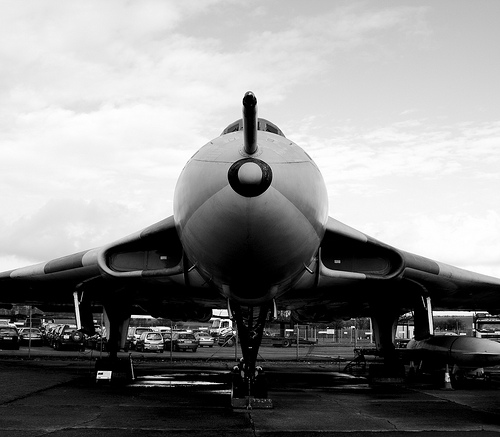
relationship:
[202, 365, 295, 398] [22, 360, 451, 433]
wheels on ground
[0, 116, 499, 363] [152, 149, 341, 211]
plane in white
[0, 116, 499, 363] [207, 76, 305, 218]
plane has sharphead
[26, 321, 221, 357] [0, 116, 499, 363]
cars parked behind plane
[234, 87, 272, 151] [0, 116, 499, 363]
nose of airplane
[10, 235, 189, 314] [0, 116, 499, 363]
leftarm of airplane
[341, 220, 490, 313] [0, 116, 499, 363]
rightarm of airplane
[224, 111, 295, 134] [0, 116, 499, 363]
windows on airplane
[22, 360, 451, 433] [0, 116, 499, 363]
landingpoint for airplane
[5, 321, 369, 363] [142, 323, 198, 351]
parkinglot for vehicles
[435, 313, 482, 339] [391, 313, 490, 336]
frontview of schoolbus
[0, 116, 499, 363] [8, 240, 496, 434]
airplane at airport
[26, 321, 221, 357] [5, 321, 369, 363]
cars parked in parkinglot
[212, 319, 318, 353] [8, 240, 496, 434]
largetruck at airport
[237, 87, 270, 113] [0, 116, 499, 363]
fronttip of airplane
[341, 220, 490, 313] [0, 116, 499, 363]
wing of airplane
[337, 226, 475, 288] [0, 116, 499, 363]
wing on airplane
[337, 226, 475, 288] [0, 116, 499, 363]
wing of plane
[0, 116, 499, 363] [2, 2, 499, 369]
plane in black and white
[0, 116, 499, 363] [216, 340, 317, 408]
plane landing gear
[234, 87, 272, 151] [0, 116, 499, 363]
nose of plane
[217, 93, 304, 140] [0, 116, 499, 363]
cockpitarea of plane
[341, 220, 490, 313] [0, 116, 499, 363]
rightwing of plane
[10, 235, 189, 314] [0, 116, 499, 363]
leftwing of plane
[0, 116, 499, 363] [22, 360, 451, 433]
plane in parkingarea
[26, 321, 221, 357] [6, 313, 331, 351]
cars in background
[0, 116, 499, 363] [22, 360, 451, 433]
plane on tarmac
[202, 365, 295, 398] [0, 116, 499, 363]
wheels of plane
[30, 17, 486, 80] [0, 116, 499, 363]
sky behind plane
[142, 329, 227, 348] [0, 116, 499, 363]
car behind plane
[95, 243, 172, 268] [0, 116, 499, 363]
propeller on plane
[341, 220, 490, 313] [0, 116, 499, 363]
wings on plane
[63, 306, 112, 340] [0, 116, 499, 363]
wings under plane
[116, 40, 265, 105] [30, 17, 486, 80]
clouds in sky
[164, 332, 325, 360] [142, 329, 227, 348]
fence in front of car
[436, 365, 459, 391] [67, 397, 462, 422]
cone on tarmac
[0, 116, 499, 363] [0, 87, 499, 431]
frontview of airplaine